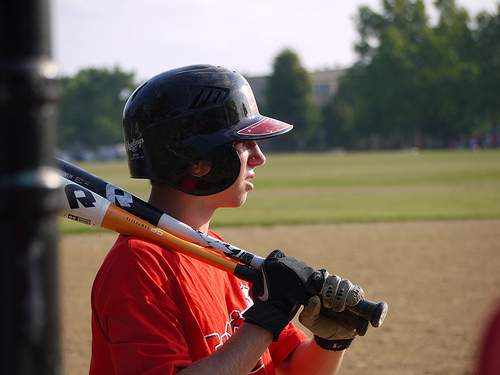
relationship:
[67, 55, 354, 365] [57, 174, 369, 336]
boy holds bat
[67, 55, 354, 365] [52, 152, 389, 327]
boy holds bat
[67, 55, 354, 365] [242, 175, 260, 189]
boy has mouth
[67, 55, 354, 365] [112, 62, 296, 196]
boy has helmet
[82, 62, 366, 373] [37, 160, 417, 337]
player holding bats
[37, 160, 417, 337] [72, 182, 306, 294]
bats holding bat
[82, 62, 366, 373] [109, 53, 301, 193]
player wearing helmet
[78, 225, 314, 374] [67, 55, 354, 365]
shirt on boy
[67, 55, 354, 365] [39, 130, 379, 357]
boy holding bats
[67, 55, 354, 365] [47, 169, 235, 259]
boy holding bats